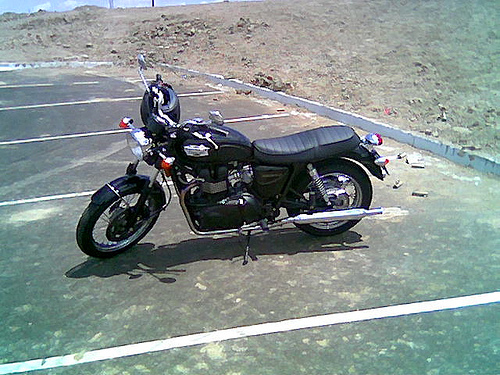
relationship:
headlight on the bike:
[116, 128, 153, 164] [84, 52, 402, 272]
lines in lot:
[4, 63, 498, 356] [3, 58, 496, 371]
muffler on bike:
[282, 207, 382, 223] [75, 55, 390, 259]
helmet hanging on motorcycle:
[139, 80, 181, 125] [71, 36, 421, 279]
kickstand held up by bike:
[235, 226, 265, 264] [75, 55, 390, 259]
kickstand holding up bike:
[242, 230, 257, 265] [66, 47, 398, 261]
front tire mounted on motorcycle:
[74, 185, 166, 257] [72, 53, 391, 266]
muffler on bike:
[265, 206, 385, 232] [66, 47, 398, 261]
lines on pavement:
[0, 63, 499, 375] [1, 60, 496, 373]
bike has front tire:
[66, 47, 398, 261] [75, 183, 162, 258]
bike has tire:
[66, 47, 398, 261] [279, 154, 379, 243]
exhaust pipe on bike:
[272, 204, 410, 233] [66, 47, 398, 261]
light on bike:
[361, 129, 388, 150] [66, 47, 398, 261]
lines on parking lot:
[0, 63, 499, 375] [1, 53, 499, 369]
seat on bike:
[250, 122, 362, 167] [66, 47, 398, 261]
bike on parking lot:
[66, 47, 398, 261] [1, 53, 499, 369]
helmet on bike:
[133, 80, 187, 132] [66, 47, 398, 261]